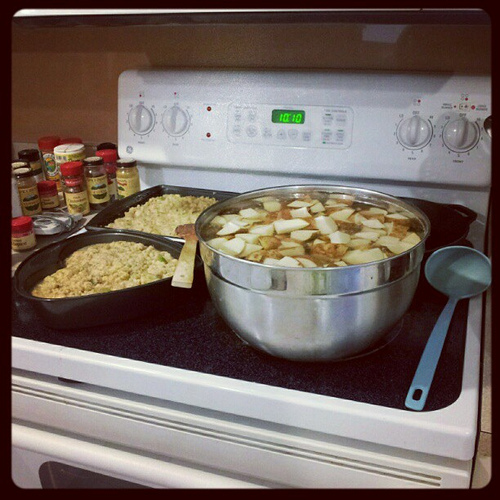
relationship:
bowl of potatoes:
[194, 184, 423, 363] [211, 192, 419, 273]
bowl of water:
[194, 184, 423, 363] [222, 194, 386, 261]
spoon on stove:
[406, 245, 491, 409] [7, 187, 481, 416]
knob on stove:
[125, 103, 151, 135] [7, 187, 481, 416]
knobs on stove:
[123, 103, 190, 137] [7, 187, 481, 416]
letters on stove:
[275, 111, 300, 125] [7, 187, 481, 416]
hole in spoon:
[413, 389, 420, 401] [406, 245, 491, 409]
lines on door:
[3, 373, 469, 500] [8, 382, 445, 492]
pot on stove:
[194, 184, 423, 363] [7, 187, 481, 416]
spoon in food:
[172, 225, 198, 287] [107, 191, 214, 247]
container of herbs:
[62, 162, 90, 221] [65, 184, 82, 190]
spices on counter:
[10, 137, 137, 258] [7, 148, 117, 322]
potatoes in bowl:
[211, 192, 419, 273] [194, 184, 423, 363]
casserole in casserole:
[37, 236, 173, 301] [10, 228, 205, 332]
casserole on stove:
[10, 228, 205, 332] [7, 187, 481, 416]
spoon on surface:
[406, 245, 491, 409] [109, 282, 462, 411]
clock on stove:
[269, 108, 308, 130] [7, 187, 481, 416]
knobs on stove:
[394, 111, 481, 151] [7, 187, 481, 416]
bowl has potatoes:
[194, 184, 423, 363] [272, 216, 310, 236]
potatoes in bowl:
[272, 216, 310, 236] [194, 184, 423, 363]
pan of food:
[90, 183, 237, 248] [107, 191, 214, 247]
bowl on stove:
[194, 184, 423, 363] [7, 187, 481, 416]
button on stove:
[321, 111, 332, 123] [7, 187, 481, 416]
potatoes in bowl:
[233, 196, 394, 253] [194, 184, 423, 363]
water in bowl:
[208, 192, 422, 265] [194, 184, 423, 363]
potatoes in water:
[233, 196, 394, 253] [208, 192, 422, 265]